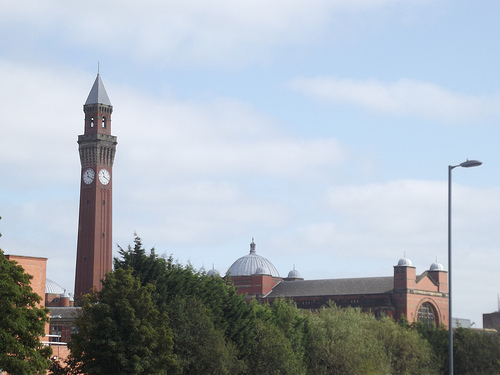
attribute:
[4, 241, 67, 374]
tree — here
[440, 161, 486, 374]
post — tall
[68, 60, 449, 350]
church — tall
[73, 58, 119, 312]
church — here, tall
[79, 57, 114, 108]
tip — steepled, red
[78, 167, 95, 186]
clock — round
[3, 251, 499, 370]
trees — green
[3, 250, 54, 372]
wall — brown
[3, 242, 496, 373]
leaves — green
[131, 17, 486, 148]
sky — blue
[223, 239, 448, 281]
domes — small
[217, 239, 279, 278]
dome — larger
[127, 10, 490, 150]
clouds — white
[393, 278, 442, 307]
bricks — red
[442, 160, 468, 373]
pole — here, metal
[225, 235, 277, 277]
lump — here